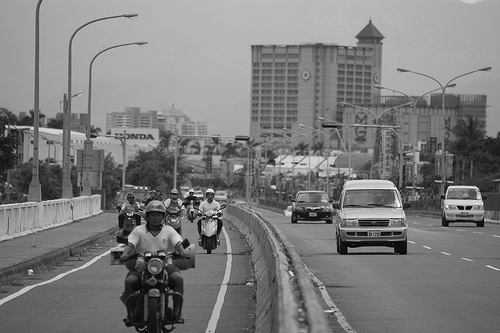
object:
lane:
[0, 211, 118, 280]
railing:
[0, 193, 103, 243]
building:
[0, 15, 489, 178]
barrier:
[222, 203, 332, 332]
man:
[184, 190, 201, 208]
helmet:
[145, 200, 167, 217]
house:
[246, 15, 389, 149]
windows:
[261, 75, 272, 81]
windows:
[337, 64, 345, 70]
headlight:
[147, 258, 164, 274]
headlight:
[344, 219, 359, 226]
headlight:
[390, 218, 402, 227]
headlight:
[474, 205, 483, 210]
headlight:
[321, 206, 331, 213]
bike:
[115, 235, 191, 333]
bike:
[193, 204, 227, 254]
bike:
[116, 205, 144, 236]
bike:
[163, 202, 187, 237]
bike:
[182, 198, 201, 223]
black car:
[290, 190, 334, 224]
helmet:
[205, 188, 214, 196]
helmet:
[170, 188, 179, 199]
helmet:
[126, 193, 134, 203]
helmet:
[189, 189, 195, 194]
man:
[120, 200, 190, 327]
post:
[60, 10, 140, 200]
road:
[0, 201, 498, 333]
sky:
[0, 0, 499, 138]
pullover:
[126, 225, 184, 266]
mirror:
[181, 238, 191, 249]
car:
[332, 180, 411, 255]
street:
[0, 169, 499, 330]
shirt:
[126, 224, 184, 257]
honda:
[115, 133, 156, 140]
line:
[0, 240, 124, 307]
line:
[204, 225, 234, 333]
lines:
[485, 264, 500, 271]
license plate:
[367, 230, 381, 238]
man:
[196, 188, 223, 235]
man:
[162, 188, 185, 215]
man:
[119, 192, 142, 217]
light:
[395, 67, 411, 73]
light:
[478, 65, 495, 72]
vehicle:
[439, 184, 488, 228]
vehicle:
[284, 206, 293, 217]